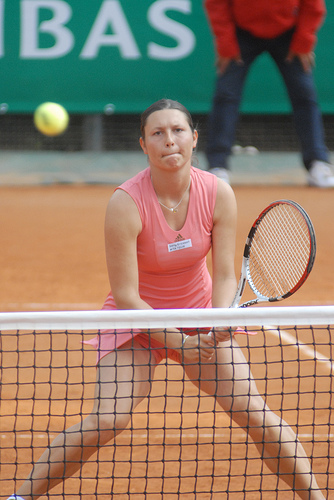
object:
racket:
[203, 199, 315, 361]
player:
[8, 98, 326, 500]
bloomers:
[96, 296, 248, 368]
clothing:
[84, 164, 219, 360]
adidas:
[175, 231, 186, 243]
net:
[0, 305, 334, 500]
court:
[0, 179, 334, 321]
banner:
[0, 0, 333, 112]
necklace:
[150, 177, 192, 214]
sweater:
[205, 0, 324, 59]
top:
[0, 306, 331, 331]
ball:
[34, 99, 70, 136]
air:
[12, 75, 98, 180]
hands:
[285, 52, 317, 72]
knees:
[213, 78, 249, 101]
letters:
[16, 0, 199, 63]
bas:
[17, 0, 192, 64]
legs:
[9, 345, 161, 500]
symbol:
[173, 231, 186, 239]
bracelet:
[178, 327, 192, 350]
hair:
[138, 97, 196, 140]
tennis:
[199, 197, 315, 365]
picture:
[0, 1, 332, 500]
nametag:
[165, 237, 195, 251]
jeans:
[205, 26, 328, 165]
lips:
[160, 150, 183, 157]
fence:
[0, 111, 334, 154]